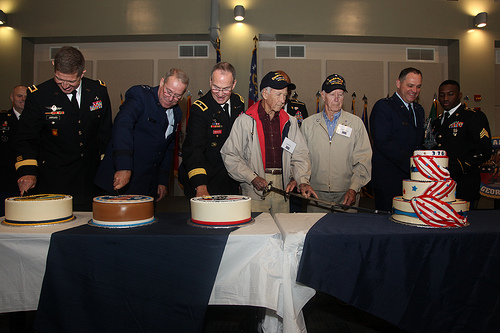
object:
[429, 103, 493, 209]
uniform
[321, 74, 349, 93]
uniform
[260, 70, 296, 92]
uniform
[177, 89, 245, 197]
uniform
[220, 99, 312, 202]
jacket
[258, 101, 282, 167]
red liner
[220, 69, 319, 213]
man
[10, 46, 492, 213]
men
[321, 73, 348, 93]
ball cap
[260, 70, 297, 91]
ball cap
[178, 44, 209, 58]
vent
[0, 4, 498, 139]
wall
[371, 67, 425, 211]
man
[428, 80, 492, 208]
man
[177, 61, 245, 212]
man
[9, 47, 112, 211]
man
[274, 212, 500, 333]
cover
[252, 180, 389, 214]
sword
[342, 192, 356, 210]
hand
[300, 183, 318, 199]
hand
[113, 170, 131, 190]
hand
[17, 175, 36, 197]
hand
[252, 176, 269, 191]
hand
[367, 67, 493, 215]
two men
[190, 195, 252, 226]
cake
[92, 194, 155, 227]
cake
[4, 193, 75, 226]
cake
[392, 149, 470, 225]
cake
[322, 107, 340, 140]
shirt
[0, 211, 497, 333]
table cloth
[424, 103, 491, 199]
military uniform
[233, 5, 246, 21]
lights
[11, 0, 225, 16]
ceiling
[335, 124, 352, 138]
name tag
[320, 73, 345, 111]
head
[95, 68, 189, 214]
man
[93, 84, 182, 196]
jacket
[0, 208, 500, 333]
men tables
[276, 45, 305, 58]
vent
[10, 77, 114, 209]
uniform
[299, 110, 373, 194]
jackets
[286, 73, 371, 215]
man